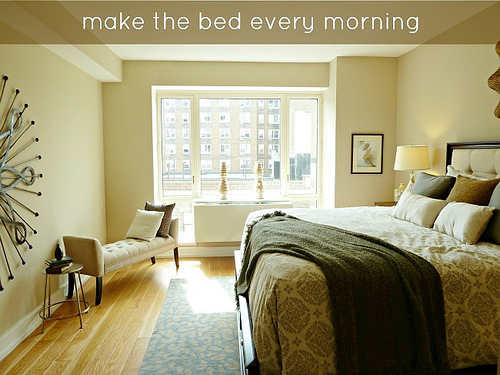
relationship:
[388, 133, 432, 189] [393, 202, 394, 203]
light on stand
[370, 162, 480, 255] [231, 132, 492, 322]
pillow on bed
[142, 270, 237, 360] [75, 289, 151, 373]
rug on floor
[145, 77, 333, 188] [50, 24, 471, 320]
window in room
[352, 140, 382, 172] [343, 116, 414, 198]
image on wall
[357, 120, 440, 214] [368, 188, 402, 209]
lamp on table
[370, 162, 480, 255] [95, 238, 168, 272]
pillow on couch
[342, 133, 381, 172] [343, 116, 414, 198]
artwork on wall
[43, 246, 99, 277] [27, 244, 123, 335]
book on stool